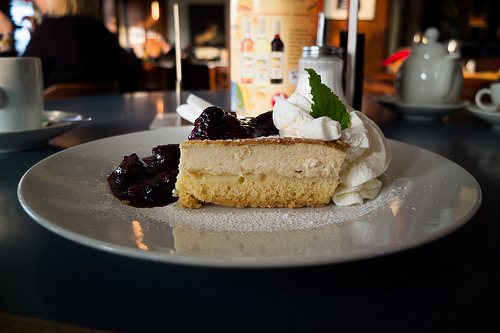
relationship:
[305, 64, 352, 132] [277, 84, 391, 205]
mint leaf on whipped cream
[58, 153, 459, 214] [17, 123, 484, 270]
powdered sugar on white dish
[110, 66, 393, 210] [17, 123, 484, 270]
dessert on whit dish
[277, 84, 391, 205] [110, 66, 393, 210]
whipped cream on dessert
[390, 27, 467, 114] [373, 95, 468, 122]
tea kettle in top of dish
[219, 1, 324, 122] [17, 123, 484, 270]
menu behind plate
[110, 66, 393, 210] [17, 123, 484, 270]
dessert on plate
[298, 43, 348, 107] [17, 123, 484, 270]
sugar jar behind dish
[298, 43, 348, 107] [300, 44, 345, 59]
sugar jar has a silver cap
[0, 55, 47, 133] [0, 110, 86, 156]
coffe mug sitting on white dish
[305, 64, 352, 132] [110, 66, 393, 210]
mint leaf on dessert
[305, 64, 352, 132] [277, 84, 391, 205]
mint leaf on top of whipped cream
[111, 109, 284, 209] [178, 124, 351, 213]
fruit topping for cake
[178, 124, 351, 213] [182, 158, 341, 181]
cake has cream filling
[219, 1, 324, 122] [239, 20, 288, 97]
menu with wine bottles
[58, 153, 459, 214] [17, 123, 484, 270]
powdered sugar on dish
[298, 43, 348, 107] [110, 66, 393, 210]
sugar jar behind dessert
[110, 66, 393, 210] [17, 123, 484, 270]
dessert on a dish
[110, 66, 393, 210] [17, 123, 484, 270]
dessert on top of dish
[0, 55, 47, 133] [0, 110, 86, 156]
coffe mug on white dish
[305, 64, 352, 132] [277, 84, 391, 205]
mint leaf in whipped cream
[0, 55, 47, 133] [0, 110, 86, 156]
coffe mug on a white dish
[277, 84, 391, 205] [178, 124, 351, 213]
whipped cream on cake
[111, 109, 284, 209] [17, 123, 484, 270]
fruit topping on dish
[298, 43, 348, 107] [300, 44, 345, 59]
sugar jar has silver cap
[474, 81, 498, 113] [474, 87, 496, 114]
tea cup with a handle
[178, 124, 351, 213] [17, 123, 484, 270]
cake on a white dish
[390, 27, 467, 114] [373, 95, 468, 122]
tea kettle on top of a dish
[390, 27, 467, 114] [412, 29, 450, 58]
tea kettle has a lid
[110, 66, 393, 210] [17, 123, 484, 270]
dessert on dish